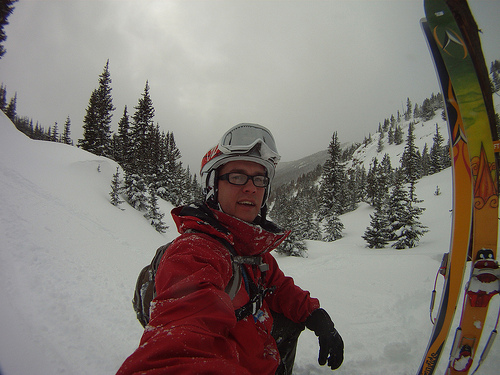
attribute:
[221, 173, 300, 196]
glasses — worn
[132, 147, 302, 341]
man — skiing, holding, taking, wearing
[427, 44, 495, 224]
skis — paired, multi-colored, yellow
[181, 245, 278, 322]
coat — red, worn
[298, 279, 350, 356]
gloves — black, dark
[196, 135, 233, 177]
helmet — worn, red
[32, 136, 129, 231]
hillside — covered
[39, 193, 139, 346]
snow — covering, white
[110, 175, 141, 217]
tree — small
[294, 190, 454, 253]
trees — covered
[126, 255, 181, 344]
backpack — brown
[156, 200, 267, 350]
jacket — red, thick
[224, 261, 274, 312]
straps — black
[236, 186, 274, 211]
mouth — open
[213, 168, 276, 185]
spectacles — paired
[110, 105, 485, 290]
valley — covered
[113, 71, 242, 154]
sky — misty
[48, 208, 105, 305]
ground — covered